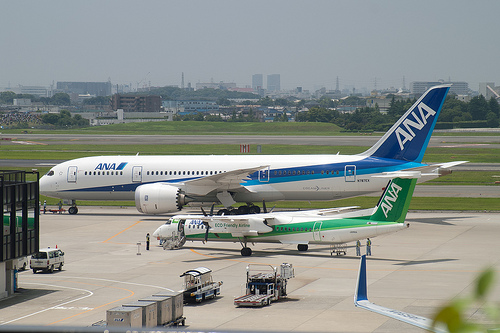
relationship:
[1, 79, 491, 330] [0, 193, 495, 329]
airport has tarmac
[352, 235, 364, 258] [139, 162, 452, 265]
person next to plane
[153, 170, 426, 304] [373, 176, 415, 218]
airline named ana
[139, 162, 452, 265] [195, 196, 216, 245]
plane has propellers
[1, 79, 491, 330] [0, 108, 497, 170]
airport has runway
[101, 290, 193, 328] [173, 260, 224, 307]
cargo on tram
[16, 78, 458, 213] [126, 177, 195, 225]
plane has engine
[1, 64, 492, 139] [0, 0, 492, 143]
city in background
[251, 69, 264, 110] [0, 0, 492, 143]
high rise building in distance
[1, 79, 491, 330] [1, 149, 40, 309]
airport has building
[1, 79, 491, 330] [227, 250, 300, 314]
airport has luggage cart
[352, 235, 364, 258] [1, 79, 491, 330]
person standing on tarmac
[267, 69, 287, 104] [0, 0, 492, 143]
tall skyscraper in distance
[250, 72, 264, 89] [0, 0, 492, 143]
high rise building in distance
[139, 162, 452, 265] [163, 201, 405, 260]
airplane has green strip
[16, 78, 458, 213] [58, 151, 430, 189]
airplane has blue strip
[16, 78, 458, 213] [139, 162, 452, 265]
airplane next to smaller plane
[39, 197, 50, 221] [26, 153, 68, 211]
person under nose of plane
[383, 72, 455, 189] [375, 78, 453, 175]
airplane rudder has stenciled ana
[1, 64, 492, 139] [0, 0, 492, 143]
city skyline in background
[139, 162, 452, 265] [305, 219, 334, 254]
airplane has an emergency exit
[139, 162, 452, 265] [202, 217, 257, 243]
airplane has eco friendly wording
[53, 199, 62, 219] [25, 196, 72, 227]
person has luggage cart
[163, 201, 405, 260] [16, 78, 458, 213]
airplane by airplane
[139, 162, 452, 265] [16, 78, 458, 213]
airplane facing same as airplane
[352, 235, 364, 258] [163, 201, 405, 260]
person next to airplane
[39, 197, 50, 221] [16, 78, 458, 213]
person next to airplane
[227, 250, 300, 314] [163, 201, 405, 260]
service vehicle near airplane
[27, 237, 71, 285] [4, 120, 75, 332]
van parked at terminal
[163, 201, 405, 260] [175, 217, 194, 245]
airplane has door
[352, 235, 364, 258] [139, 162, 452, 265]
person behind airplane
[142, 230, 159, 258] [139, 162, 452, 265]
person in front of airplane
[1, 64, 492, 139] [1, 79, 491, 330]
city behind airport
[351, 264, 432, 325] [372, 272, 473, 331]
wing in corner